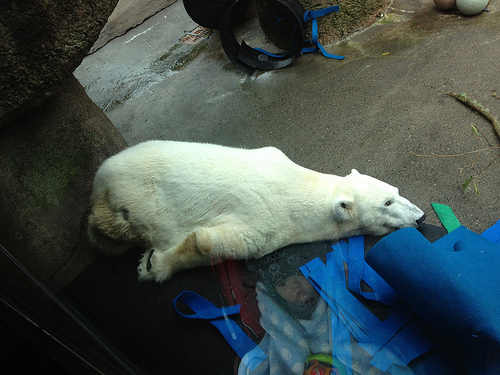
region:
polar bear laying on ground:
[87, 137, 348, 256]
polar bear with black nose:
[406, 210, 421, 230]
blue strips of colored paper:
[302, 263, 398, 348]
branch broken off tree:
[407, 111, 495, 177]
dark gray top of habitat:
[35, 33, 94, 76]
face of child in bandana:
[248, 248, 332, 331]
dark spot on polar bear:
[85, 196, 144, 241]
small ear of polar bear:
[327, 189, 357, 229]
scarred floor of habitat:
[119, 45, 194, 87]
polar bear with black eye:
[379, 195, 389, 212]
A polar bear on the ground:
[93, 140, 423, 278]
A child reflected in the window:
[253, 243, 321, 312]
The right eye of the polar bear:
[379, 197, 393, 212]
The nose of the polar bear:
[416, 209, 428, 224]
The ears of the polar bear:
[338, 168, 358, 213]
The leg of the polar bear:
[138, 218, 235, 278]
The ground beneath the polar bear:
[67, 0, 498, 373]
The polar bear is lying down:
[88, 137, 425, 280]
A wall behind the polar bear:
[0, 71, 138, 287]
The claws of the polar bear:
[136, 251, 156, 278]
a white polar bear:
[64, 133, 432, 282]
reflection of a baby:
[251, 235, 386, 372]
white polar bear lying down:
[90, 132, 440, 277]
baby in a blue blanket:
[248, 248, 415, 373]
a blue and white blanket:
[251, 286, 401, 372]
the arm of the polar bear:
[131, 225, 255, 282]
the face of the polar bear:
[370, 182, 432, 238]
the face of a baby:
[262, 252, 329, 304]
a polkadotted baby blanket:
[248, 282, 400, 371]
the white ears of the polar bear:
[329, 160, 367, 217]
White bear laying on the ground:
[81, 137, 428, 284]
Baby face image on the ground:
[242, 245, 329, 311]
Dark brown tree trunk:
[3, 3, 123, 145]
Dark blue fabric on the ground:
[365, 227, 497, 349]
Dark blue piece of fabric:
[165, 287, 267, 367]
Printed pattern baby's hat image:
[246, 244, 315, 285]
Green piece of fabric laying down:
[427, 196, 466, 233]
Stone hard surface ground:
[263, 75, 409, 142]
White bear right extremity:
[129, 225, 255, 284]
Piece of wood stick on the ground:
[438, 80, 497, 140]